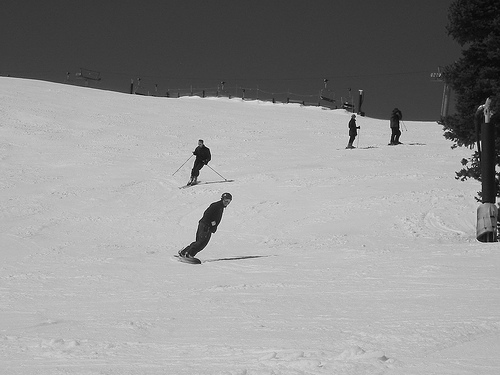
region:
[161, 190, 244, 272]
snowboarder tilted to one side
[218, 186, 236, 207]
black helmet on snowboarder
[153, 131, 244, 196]
skier descending snowy hill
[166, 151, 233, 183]
two poles on skier's hands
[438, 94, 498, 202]
evergreen tree on side of hill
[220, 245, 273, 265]
snowboarder shadow in snow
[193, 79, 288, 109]
fence at top of hill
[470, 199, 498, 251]
cover around tree trunk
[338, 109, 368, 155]
skier standing near top of hill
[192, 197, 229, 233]
winter coat on snowboarder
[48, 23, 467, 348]
There are people on the ski slope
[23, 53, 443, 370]
There is snow on the ground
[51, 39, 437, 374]
There are people on a snowboard or skis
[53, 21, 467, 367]
The man in front is on a snowboard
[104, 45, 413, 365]
The man behind the snowboarder is on skis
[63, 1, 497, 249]
There is a tree in the background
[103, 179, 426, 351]
The snowboarder is going down the ski slope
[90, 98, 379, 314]
The skier is going down the ski slope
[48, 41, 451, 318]
There is a ski lift in the background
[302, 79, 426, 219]
There are people standing on the ski slope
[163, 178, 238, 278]
Snowboarder on a hill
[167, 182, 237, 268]
Snowboarder wears black helmet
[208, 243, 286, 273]
Shadow of snowboarder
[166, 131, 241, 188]
Skier has black suit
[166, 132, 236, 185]
Skier holds snow poles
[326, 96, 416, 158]
Two skiers on the hill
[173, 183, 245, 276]
Skier is inclined forward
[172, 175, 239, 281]
Skier wears a black jacket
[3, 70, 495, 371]
Hill is cover with snow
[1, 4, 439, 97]
The sky is dark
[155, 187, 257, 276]
This person is snowboarding.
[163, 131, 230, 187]
This person is skiing.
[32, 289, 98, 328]
The snow is white.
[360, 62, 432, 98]
Wires for the ski lift.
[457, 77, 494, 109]
Tree on the ski slope.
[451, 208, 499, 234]
Protective pipe around the tree.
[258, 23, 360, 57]
The sky is dark grey.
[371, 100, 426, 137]
Person is putting their hat on.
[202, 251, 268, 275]
Shadow the snowboarder is casting.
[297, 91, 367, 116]
Seats on the ski lift.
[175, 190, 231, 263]
person in black riding snowboard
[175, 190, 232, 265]
snowboarder leaning forward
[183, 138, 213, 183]
person skiing behind snowboarder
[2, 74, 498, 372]
ground covered in white snow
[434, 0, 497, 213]
evergreen tree near skiiers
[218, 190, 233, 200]
snowboarder wearing black cap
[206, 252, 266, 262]
shadow of snowboarder in snow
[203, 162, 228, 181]
skier holding ski pole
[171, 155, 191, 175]
skier holding ski pole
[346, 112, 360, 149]
skier standing toward top of hill